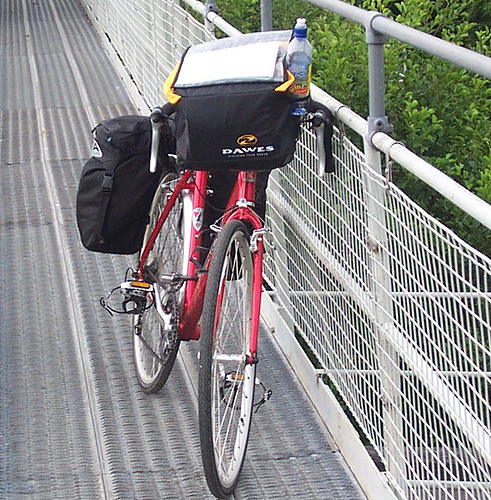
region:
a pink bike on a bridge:
[102, 102, 339, 481]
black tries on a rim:
[175, 217, 275, 495]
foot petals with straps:
[112, 271, 161, 317]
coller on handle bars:
[170, 22, 326, 179]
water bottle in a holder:
[288, 17, 314, 127]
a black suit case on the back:
[76, 120, 278, 249]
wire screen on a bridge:
[319, 203, 443, 424]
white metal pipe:
[358, 111, 420, 459]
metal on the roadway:
[41, 283, 133, 451]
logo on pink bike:
[187, 190, 217, 245]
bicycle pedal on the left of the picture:
[97, 275, 171, 347]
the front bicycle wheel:
[188, 214, 272, 495]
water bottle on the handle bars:
[289, 15, 324, 120]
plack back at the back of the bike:
[70, 100, 189, 263]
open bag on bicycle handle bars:
[159, 29, 325, 195]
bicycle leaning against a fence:
[77, 23, 321, 497]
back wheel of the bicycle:
[122, 172, 195, 397]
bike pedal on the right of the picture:
[216, 362, 277, 417]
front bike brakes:
[205, 200, 271, 263]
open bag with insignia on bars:
[161, 35, 317, 199]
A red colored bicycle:
[120, 97, 338, 493]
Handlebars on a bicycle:
[138, 93, 339, 179]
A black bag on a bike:
[73, 114, 183, 257]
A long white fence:
[82, 0, 488, 498]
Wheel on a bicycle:
[194, 216, 266, 493]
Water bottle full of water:
[282, 10, 319, 125]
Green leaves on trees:
[211, 0, 487, 258]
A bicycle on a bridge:
[3, 2, 482, 494]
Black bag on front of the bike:
[163, 39, 303, 166]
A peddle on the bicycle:
[113, 263, 166, 310]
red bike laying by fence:
[84, 87, 333, 485]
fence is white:
[83, 4, 483, 492]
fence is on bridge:
[128, 13, 483, 491]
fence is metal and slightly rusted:
[77, 0, 482, 495]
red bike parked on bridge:
[125, 164, 290, 356]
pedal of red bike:
[108, 277, 161, 301]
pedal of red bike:
[218, 368, 268, 404]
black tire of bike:
[193, 220, 258, 489]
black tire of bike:
[133, 189, 190, 390]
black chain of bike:
[136, 289, 180, 360]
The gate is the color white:
[370, 144, 486, 494]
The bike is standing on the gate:
[78, 15, 334, 494]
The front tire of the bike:
[191, 214, 274, 497]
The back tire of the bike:
[116, 167, 193, 395]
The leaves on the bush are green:
[398, 57, 485, 170]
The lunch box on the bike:
[163, 16, 316, 178]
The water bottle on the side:
[284, 11, 317, 118]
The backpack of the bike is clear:
[73, 109, 167, 256]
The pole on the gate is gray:
[341, 5, 486, 115]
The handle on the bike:
[142, 101, 170, 176]